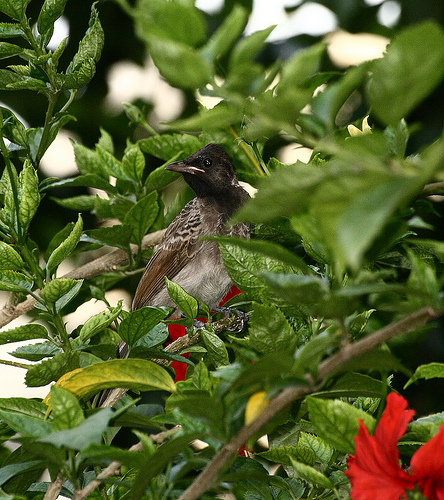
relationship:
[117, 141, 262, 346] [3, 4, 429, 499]
bird on plant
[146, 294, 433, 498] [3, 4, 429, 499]
branch in plant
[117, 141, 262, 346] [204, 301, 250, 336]
bird has claw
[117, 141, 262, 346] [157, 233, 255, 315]
bird has belly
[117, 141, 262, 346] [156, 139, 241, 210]
bird has head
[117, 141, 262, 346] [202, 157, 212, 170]
bird has eye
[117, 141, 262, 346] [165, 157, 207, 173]
bird has beak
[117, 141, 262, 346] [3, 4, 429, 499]
bird sitting on plant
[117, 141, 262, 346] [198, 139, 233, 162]
bird has mohawk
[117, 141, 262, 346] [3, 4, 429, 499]
bird in plant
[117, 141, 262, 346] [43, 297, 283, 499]
bird on branch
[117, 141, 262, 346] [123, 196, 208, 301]
bird has wing